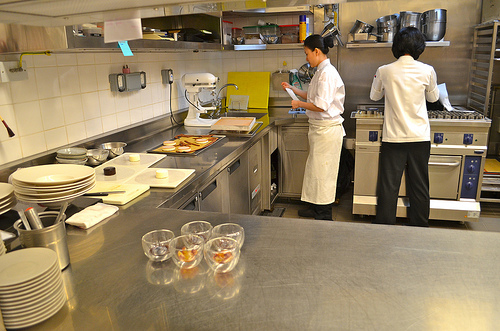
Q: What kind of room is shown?
A: It is a kitchen.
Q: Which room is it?
A: It is a kitchen.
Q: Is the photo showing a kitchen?
A: Yes, it is showing a kitchen.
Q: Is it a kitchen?
A: Yes, it is a kitchen.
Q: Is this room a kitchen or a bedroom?
A: It is a kitchen.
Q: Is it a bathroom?
A: No, it is a kitchen.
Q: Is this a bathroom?
A: No, it is a kitchen.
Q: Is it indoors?
A: Yes, it is indoors.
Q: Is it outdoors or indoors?
A: It is indoors.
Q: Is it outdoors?
A: No, it is indoors.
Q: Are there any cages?
A: No, there are no cages.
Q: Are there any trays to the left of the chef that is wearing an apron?
A: Yes, there is a tray to the left of the chef.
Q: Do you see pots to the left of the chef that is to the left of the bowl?
A: No, there is a tray to the left of the chef.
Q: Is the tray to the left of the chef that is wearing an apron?
A: Yes, the tray is to the left of the chef.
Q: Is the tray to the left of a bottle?
A: No, the tray is to the left of the chef.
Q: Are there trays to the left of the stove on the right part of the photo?
A: Yes, there is a tray to the left of the stove.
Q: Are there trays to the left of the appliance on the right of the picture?
A: Yes, there is a tray to the left of the stove.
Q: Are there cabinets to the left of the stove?
A: No, there is a tray to the left of the stove.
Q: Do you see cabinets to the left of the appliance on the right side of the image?
A: No, there is a tray to the left of the stove.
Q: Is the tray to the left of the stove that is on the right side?
A: Yes, the tray is to the left of the stove.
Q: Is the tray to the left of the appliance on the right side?
A: Yes, the tray is to the left of the stove.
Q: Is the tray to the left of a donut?
A: No, the tray is to the left of the stove.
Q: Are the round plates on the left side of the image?
A: Yes, the plates are on the left of the image.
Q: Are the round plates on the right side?
A: No, the plates are on the left of the image.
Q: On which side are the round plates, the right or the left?
A: The plates are on the left of the image.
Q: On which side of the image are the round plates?
A: The plates are on the left of the image.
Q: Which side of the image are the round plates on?
A: The plates are on the left of the image.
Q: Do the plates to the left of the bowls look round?
A: Yes, the plates are round.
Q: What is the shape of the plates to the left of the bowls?
A: The plates are round.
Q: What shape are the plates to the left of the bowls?
A: The plates are round.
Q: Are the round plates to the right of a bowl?
A: No, the plates are to the left of a bowl.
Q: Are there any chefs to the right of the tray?
A: Yes, there is a chef to the right of the tray.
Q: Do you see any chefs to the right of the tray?
A: Yes, there is a chef to the right of the tray.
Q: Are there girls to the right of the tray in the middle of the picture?
A: No, there is a chef to the right of the tray.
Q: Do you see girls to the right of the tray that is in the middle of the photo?
A: No, there is a chef to the right of the tray.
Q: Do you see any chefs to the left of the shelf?
A: Yes, there is a chef to the left of the shelf.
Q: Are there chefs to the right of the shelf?
A: No, the chef is to the left of the shelf.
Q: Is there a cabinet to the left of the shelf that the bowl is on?
A: No, there is a chef to the left of the shelf.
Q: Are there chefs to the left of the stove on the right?
A: Yes, there is a chef to the left of the stove.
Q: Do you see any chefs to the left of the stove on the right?
A: Yes, there is a chef to the left of the stove.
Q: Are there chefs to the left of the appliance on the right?
A: Yes, there is a chef to the left of the stove.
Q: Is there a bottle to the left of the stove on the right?
A: No, there is a chef to the left of the stove.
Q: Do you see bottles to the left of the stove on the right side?
A: No, there is a chef to the left of the stove.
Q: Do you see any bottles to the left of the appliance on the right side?
A: No, there is a chef to the left of the stove.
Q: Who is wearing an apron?
A: The chef is wearing an apron.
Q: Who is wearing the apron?
A: The chef is wearing an apron.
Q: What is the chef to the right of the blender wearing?
A: The chef is wearing an apron.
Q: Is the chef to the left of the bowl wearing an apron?
A: Yes, the chef is wearing an apron.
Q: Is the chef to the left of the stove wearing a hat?
A: No, the chef is wearing an apron.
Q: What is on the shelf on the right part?
A: The bowl is on the shelf.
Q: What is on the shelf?
A: The bowl is on the shelf.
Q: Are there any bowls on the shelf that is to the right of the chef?
A: Yes, there is a bowl on the shelf.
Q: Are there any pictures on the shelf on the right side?
A: No, there is a bowl on the shelf.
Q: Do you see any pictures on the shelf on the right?
A: No, there is a bowl on the shelf.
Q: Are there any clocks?
A: No, there are no clocks.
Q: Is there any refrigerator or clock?
A: No, there are no clocks or refrigerators.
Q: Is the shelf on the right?
A: Yes, the shelf is on the right of the image.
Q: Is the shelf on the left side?
A: No, the shelf is on the right of the image.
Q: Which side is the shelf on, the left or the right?
A: The shelf is on the right of the image.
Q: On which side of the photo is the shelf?
A: The shelf is on the right of the image.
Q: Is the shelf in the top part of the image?
A: Yes, the shelf is in the top of the image.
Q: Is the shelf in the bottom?
A: No, the shelf is in the top of the image.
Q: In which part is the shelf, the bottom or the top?
A: The shelf is in the top of the image.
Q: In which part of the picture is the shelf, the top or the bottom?
A: The shelf is in the top of the image.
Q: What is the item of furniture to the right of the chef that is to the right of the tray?
A: The piece of furniture is a shelf.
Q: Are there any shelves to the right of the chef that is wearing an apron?
A: Yes, there is a shelf to the right of the chef.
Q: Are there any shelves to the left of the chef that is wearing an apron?
A: No, the shelf is to the right of the chef.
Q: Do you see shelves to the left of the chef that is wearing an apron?
A: No, the shelf is to the right of the chef.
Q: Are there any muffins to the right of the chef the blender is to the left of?
A: No, there is a shelf to the right of the chef.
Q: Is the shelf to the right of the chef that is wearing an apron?
A: Yes, the shelf is to the right of the chef.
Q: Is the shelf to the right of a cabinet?
A: No, the shelf is to the right of the chef.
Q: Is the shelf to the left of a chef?
A: No, the shelf is to the right of a chef.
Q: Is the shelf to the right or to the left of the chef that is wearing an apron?
A: The shelf is to the right of the chef.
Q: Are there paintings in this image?
A: No, there are no paintings.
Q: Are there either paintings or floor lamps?
A: No, there are no paintings or floor lamps.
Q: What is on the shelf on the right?
A: The bowl is on the shelf.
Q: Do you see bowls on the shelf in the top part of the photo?
A: Yes, there is a bowl on the shelf.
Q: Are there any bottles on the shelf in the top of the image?
A: No, there is a bowl on the shelf.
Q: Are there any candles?
A: No, there are no candles.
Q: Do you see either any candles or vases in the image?
A: No, there are no candles or vases.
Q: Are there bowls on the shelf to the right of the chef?
A: Yes, there is a bowl on the shelf.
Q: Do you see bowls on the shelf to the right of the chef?
A: Yes, there is a bowl on the shelf.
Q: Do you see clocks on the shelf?
A: No, there is a bowl on the shelf.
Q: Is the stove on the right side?
A: Yes, the stove is on the right of the image.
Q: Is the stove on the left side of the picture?
A: No, the stove is on the right of the image.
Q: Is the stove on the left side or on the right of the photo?
A: The stove is on the right of the image.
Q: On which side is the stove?
A: The stove is on the right of the image.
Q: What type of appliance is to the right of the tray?
A: The appliance is a stove.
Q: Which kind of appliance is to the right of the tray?
A: The appliance is a stove.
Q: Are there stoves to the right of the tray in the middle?
A: Yes, there is a stove to the right of the tray.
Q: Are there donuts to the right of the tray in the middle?
A: No, there is a stove to the right of the tray.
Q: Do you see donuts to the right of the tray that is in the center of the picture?
A: No, there is a stove to the right of the tray.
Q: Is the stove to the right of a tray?
A: Yes, the stove is to the right of a tray.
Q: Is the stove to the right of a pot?
A: No, the stove is to the right of a tray.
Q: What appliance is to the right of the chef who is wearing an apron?
A: The appliance is a stove.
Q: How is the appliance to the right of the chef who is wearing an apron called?
A: The appliance is a stove.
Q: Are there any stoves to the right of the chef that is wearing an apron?
A: Yes, there is a stove to the right of the chef.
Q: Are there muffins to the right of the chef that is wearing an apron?
A: No, there is a stove to the right of the chef.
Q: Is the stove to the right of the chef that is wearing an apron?
A: Yes, the stove is to the right of the chef.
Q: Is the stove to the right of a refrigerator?
A: No, the stove is to the right of the chef.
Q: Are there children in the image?
A: No, there are no children.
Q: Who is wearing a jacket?
A: The chef is wearing a jacket.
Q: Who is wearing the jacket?
A: The chef is wearing a jacket.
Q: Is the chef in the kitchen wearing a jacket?
A: Yes, the chef is wearing a jacket.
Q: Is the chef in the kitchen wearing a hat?
A: No, the chef is wearing a jacket.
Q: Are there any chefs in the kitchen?
A: Yes, there is a chef in the kitchen.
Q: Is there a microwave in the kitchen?
A: No, there is a chef in the kitchen.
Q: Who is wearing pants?
A: The chef is wearing pants.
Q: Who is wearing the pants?
A: The chef is wearing pants.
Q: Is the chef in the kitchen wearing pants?
A: Yes, the chef is wearing pants.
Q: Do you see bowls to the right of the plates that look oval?
A: Yes, there is a bowl to the right of the plates.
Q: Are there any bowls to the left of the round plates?
A: No, the bowl is to the right of the plates.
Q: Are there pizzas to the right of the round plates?
A: No, there is a bowl to the right of the plates.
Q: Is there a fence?
A: No, there are no fences.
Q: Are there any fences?
A: No, there are no fences.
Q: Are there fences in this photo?
A: No, there are no fences.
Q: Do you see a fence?
A: No, there are no fences.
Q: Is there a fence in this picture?
A: No, there are no fences.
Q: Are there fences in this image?
A: No, there are no fences.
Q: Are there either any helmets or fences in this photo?
A: No, there are no fences or helmets.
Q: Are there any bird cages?
A: No, there are no bird cages.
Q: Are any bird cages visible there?
A: No, there are no bird cages.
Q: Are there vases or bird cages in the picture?
A: No, there are no bird cages or vases.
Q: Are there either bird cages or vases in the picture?
A: No, there are no bird cages or vases.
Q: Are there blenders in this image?
A: Yes, there is a blender.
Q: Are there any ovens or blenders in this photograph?
A: Yes, there is a blender.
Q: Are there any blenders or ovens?
A: Yes, there is a blender.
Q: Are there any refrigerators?
A: No, there are no refrigerators.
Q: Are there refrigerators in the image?
A: No, there are no refrigerators.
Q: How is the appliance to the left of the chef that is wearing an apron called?
A: The appliance is a blender.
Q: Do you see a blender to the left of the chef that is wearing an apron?
A: Yes, there is a blender to the left of the chef.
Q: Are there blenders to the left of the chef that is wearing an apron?
A: Yes, there is a blender to the left of the chef.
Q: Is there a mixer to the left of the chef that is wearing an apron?
A: No, there is a blender to the left of the chef.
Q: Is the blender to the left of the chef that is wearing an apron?
A: Yes, the blender is to the left of the chef.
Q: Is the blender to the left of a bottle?
A: No, the blender is to the left of the chef.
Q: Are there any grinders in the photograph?
A: No, there are no grinders.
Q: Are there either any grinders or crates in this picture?
A: No, there are no grinders or crates.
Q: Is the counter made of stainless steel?
A: Yes, the counter is made of stainless steel.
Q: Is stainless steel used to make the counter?
A: Yes, the counter is made of stainless steel.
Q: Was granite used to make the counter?
A: No, the counter is made of stainless steel.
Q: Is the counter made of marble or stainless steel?
A: The counter is made of stainless steel.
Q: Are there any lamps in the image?
A: No, there are no lamps.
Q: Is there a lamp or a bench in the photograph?
A: No, there are no lamps or benches.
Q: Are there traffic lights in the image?
A: No, there are no traffic lights.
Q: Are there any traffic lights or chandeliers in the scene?
A: No, there are no traffic lights or chandeliers.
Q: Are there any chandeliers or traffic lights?
A: No, there are no traffic lights or chandeliers.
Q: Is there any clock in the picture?
A: No, there are no clocks.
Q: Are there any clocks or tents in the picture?
A: No, there are no clocks or tents.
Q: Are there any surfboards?
A: No, there are no surfboards.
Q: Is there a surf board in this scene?
A: No, there are no surfboards.